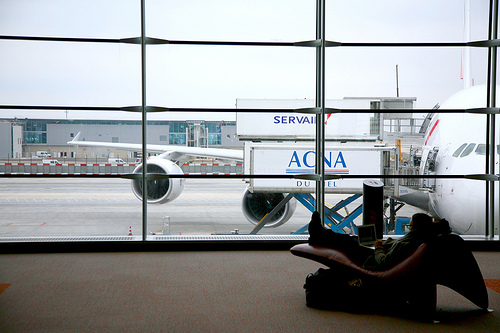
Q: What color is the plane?
A: White.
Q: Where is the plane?
A: On the cement.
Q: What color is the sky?
A: Gray.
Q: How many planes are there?
A: One.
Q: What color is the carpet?
A: Tan.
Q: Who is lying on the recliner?
A: The woman.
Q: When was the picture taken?
A: Daytime.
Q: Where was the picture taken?
A: At an airport.